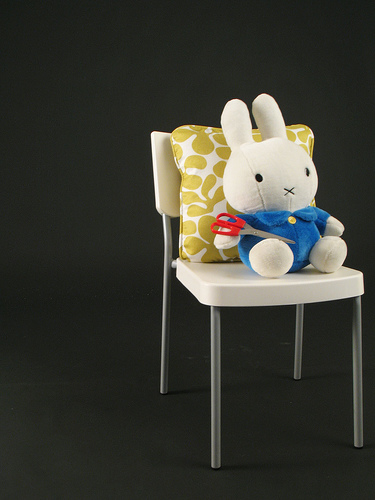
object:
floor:
[0, 319, 375, 500]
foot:
[244, 238, 301, 281]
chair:
[133, 99, 374, 472]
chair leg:
[206, 307, 231, 472]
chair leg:
[291, 294, 308, 384]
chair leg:
[342, 292, 366, 452]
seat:
[170, 244, 373, 311]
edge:
[200, 274, 370, 296]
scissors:
[203, 203, 302, 247]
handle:
[208, 204, 250, 240]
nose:
[282, 185, 299, 198]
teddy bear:
[212, 94, 349, 279]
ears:
[212, 91, 259, 154]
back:
[152, 130, 195, 215]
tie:
[257, 207, 321, 225]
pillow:
[167, 104, 331, 278]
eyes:
[252, 170, 266, 185]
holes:
[218, 215, 235, 223]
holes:
[214, 224, 233, 233]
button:
[287, 215, 299, 226]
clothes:
[231, 203, 333, 285]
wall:
[1, 1, 375, 296]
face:
[225, 132, 322, 214]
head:
[216, 79, 326, 221]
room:
[1, 3, 374, 495]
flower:
[186, 180, 222, 216]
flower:
[288, 125, 315, 152]